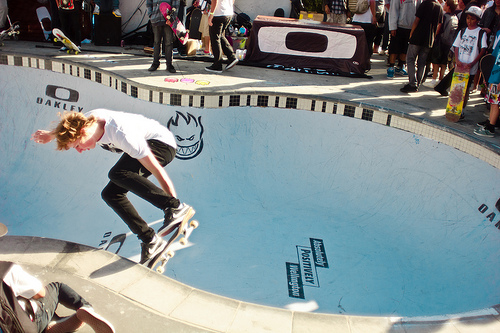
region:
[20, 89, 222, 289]
young man doing skateboard trick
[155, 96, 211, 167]
drawing of smiling fireball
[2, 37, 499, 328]
an empty pool used for skateboarding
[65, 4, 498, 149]
group of people watching skateboarder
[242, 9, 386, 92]
a desk used by skateboard personel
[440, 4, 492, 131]
young boy holding a skateboard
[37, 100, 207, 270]
boy holding skateboard with one hand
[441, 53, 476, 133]
yellow and red skateboard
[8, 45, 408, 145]
black and white striped edge of pool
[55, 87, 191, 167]
boy wearing a white t-shirt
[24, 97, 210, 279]
A skateboarder doing a trick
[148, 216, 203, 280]
A black skateboard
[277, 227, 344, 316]
Writing in the pool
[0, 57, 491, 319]
An empty pool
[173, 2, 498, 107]
A crowd watching the event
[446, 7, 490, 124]
A young child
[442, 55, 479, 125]
A yellow skateboard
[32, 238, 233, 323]
Grey edge of the pool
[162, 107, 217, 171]
A decal in the pool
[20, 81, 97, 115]
The advertisement says "Oakley"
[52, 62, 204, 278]
a man in white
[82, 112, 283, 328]
a man in white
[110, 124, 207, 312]
a man in white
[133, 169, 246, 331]
a man in white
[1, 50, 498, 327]
empty pool for skating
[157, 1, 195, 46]
pink colored skateboard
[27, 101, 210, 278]
boy on a skateboard in a pool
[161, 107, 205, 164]
logo of a face in the pool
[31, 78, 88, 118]
oakley logo in the pool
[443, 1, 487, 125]
boy with a yellow skateboard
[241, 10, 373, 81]
table with black and white table cloth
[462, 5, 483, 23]
white hat on boy's head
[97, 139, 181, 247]
black pants on skater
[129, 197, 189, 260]
skater's black nike shoes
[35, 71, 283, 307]
a man skateboarding outside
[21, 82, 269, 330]
a man skateboarding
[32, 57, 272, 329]
a man on a skateboard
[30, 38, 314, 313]
a man skateboarding in an empty pool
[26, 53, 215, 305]
a man with long hair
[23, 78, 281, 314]
a man wearing a shirt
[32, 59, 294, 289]
a man wearing a white shirt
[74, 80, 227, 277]
a man bent forward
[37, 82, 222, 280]
a man wearing pants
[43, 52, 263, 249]
a man wearing shoes